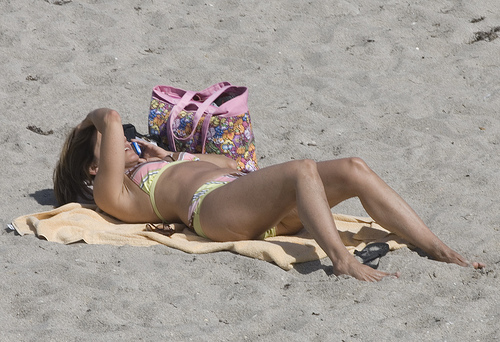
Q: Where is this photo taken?
A: On a beach.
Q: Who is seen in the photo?
A: A lady.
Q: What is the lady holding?
A: A cellphone.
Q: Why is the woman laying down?
A: She is trying to get a tan.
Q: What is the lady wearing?
A: A bathing suit.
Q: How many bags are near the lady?
A: One.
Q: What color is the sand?
A: Gray.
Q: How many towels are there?
A: One.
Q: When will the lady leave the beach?
A: After she has finished tanning.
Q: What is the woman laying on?
A: Towel.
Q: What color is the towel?
A: Yellow.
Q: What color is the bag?
A: Pink.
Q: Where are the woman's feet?
A: Sand.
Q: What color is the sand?
A: Grey.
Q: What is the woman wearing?
A: Bikini.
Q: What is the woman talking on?
A: Cell phone.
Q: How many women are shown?
A: One.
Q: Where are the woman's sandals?
A: Between legs.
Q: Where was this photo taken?
A: The beach.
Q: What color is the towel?
A: Yellow.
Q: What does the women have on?
A: A bikini.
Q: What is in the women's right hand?
A: A cellular phone.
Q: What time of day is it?
A: Afternoon.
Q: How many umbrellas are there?
A: None.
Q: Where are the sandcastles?
A: There are none.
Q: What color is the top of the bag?
A: Pink.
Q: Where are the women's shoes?
A: Under her legs.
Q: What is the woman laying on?
A: Towel.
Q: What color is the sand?
A: Grey.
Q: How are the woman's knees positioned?
A: Bent.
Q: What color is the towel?
A: Orange.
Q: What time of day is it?
A: Daytime.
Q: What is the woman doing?
A: On the phone.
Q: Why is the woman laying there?
A: Tanning.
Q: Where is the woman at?
A: Beach.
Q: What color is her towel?
A: Peach.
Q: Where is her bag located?
A: To her left.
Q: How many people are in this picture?
A: One.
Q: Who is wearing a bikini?
A: The woman.